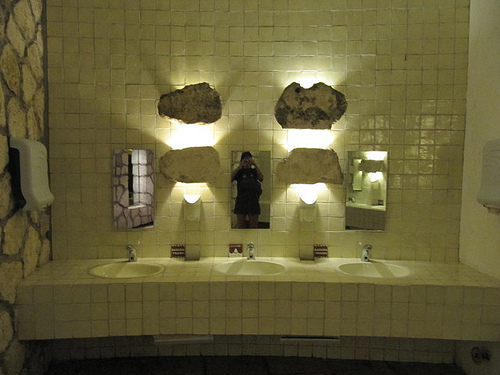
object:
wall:
[2, 1, 499, 364]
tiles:
[243, 71, 258, 86]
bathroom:
[0, 0, 500, 372]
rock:
[2, 2, 52, 372]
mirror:
[227, 149, 274, 231]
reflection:
[231, 151, 266, 230]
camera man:
[230, 151, 264, 229]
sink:
[336, 261, 410, 278]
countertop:
[15, 256, 499, 289]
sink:
[215, 259, 289, 277]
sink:
[86, 261, 167, 280]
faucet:
[361, 244, 374, 262]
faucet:
[246, 241, 257, 260]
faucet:
[125, 242, 138, 262]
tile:
[274, 282, 292, 302]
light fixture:
[182, 193, 203, 232]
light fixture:
[299, 192, 320, 224]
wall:
[0, 0, 55, 374]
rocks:
[0, 301, 18, 354]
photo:
[0, 0, 497, 374]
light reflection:
[395, 106, 455, 189]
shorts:
[233, 194, 261, 216]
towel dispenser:
[7, 132, 57, 213]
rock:
[273, 80, 350, 130]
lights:
[298, 135, 302, 139]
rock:
[157, 80, 223, 125]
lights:
[172, 136, 178, 138]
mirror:
[345, 150, 390, 233]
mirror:
[111, 147, 157, 232]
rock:
[274, 146, 345, 186]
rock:
[156, 145, 222, 184]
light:
[284, 131, 338, 145]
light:
[156, 124, 223, 152]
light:
[289, 182, 334, 204]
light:
[173, 180, 212, 204]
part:
[43, 3, 105, 53]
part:
[184, 202, 194, 207]